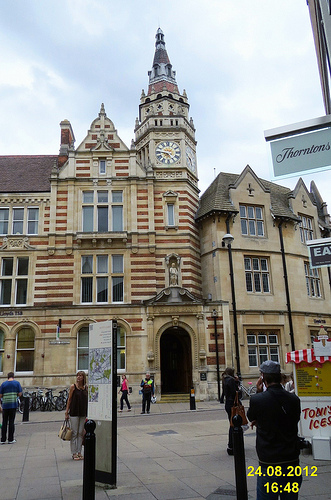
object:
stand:
[284, 328, 330, 459]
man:
[247, 351, 300, 499]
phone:
[257, 371, 265, 391]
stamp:
[245, 461, 318, 498]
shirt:
[0, 377, 23, 413]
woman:
[63, 372, 87, 459]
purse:
[59, 409, 76, 441]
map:
[87, 322, 113, 423]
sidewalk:
[2, 421, 326, 500]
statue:
[166, 257, 181, 289]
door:
[160, 321, 191, 396]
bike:
[45, 388, 71, 411]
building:
[0, 27, 330, 399]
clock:
[152, 137, 182, 165]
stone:
[156, 452, 194, 472]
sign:
[269, 127, 330, 181]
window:
[81, 190, 121, 231]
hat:
[258, 357, 285, 373]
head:
[74, 367, 87, 387]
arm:
[64, 381, 75, 415]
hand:
[62, 410, 72, 423]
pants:
[69, 416, 84, 457]